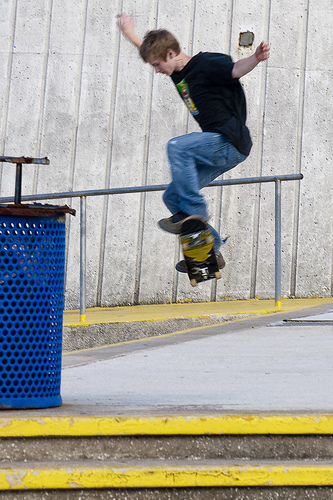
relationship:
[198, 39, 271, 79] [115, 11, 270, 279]
arm balancing boy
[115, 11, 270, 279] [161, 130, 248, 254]
boy wearing jeans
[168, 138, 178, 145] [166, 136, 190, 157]
hole revealing knee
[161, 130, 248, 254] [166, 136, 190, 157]
jeans covering knee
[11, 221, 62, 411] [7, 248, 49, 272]
bin has holes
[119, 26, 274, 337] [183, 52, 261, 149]
boy wearing shirt